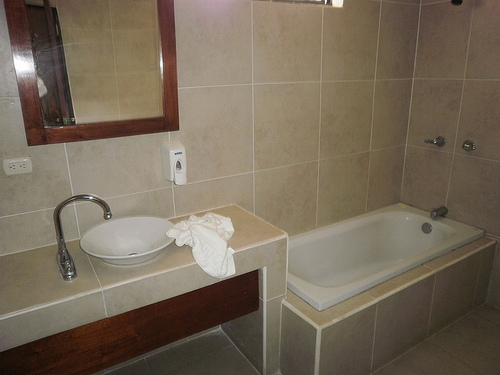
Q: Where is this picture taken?
A: A bathroom.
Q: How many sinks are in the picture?
A: One.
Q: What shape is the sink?
A: Round.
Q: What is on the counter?
A: A towel.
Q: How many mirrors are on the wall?
A: One.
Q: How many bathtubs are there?
A: One.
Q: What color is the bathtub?
A: White.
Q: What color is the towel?
A: White.